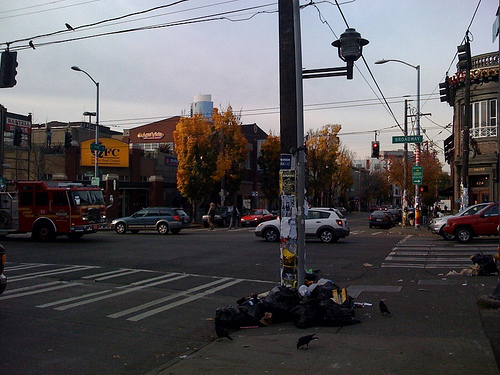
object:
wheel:
[317, 223, 338, 243]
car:
[254, 205, 350, 242]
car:
[442, 201, 500, 242]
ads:
[278, 167, 297, 195]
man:
[298, 272, 360, 324]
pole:
[278, 0, 305, 297]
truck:
[0, 179, 107, 242]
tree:
[303, 124, 341, 206]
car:
[109, 207, 192, 235]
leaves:
[185, 139, 200, 152]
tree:
[172, 103, 233, 224]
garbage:
[215, 277, 360, 329]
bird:
[295, 329, 320, 349]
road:
[0, 211, 499, 374]